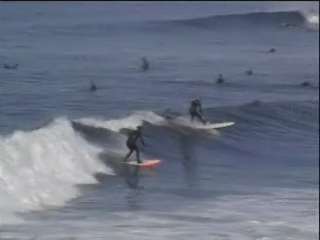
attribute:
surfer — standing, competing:
[120, 123, 161, 168]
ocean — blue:
[1, 0, 319, 240]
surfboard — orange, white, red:
[125, 158, 161, 167]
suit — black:
[123, 128, 145, 161]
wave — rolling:
[0, 91, 316, 207]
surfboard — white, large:
[190, 120, 236, 130]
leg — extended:
[194, 113, 209, 126]